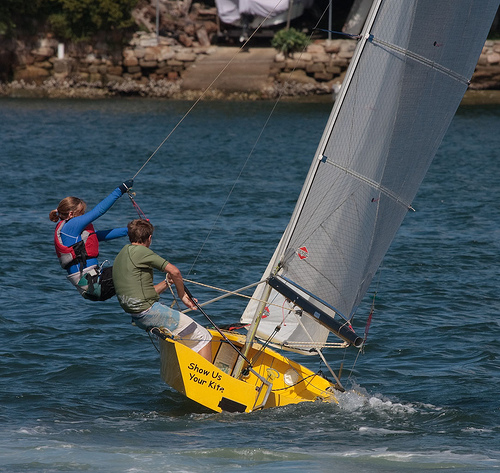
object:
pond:
[0, 96, 499, 471]